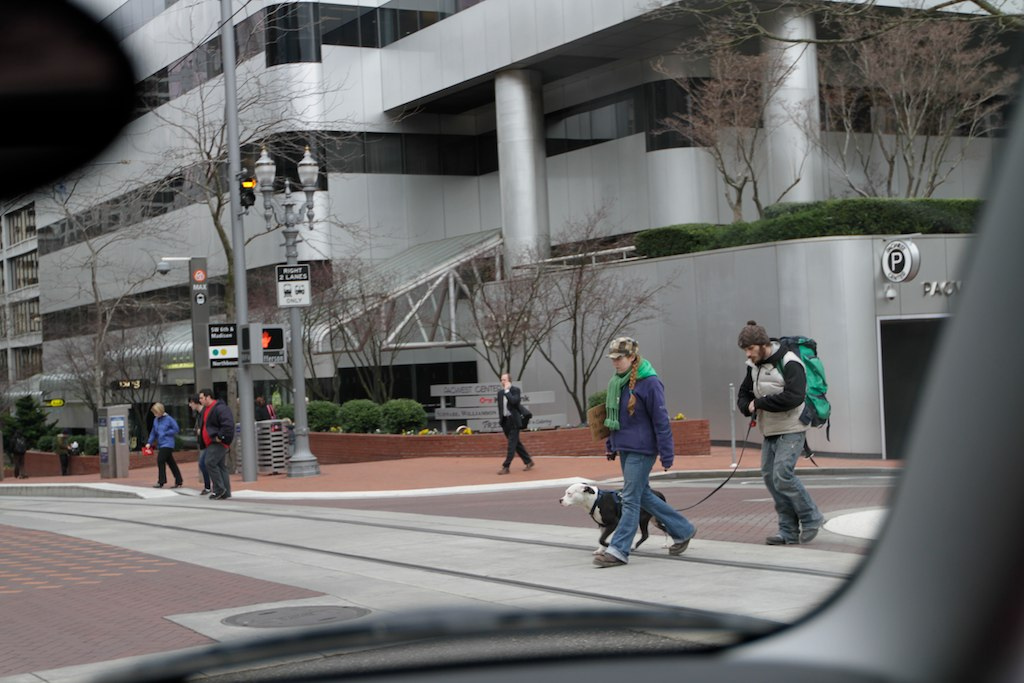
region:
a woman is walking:
[596, 340, 695, 560]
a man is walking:
[734, 321, 833, 534]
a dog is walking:
[561, 480, 660, 554]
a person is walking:
[494, 371, 532, 474]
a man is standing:
[196, 385, 236, 503]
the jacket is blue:
[147, 410, 179, 450]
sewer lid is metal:
[226, 599, 364, 631]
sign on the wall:
[880, 240, 919, 278]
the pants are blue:
[760, 436, 818, 528]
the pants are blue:
[608, 456, 688, 556]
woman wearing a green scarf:
[593, 337, 699, 566]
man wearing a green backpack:
[726, 319, 845, 547]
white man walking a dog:
[555, 318, 837, 562]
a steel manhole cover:
[215, 590, 383, 632]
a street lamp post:
[249, 142, 339, 476]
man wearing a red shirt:
[190, 386, 236, 501]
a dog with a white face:
[556, 478, 670, 556]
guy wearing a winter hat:
[735, 313, 838, 548]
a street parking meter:
[87, 397, 139, 487]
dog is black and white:
[559, 477, 668, 547]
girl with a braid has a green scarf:
[591, 338, 694, 566]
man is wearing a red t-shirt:
[198, 388, 238, 502]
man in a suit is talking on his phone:
[499, 372, 539, 472]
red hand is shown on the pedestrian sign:
[259, 323, 285, 361]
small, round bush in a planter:
[376, 398, 435, 431]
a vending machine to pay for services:
[97, 399, 139, 480]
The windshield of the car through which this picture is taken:
[4, 4, 1020, 663]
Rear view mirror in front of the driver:
[4, 5, 145, 215]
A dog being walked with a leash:
[562, 479, 670, 547]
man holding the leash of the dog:
[737, 320, 821, 548]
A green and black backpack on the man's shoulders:
[800, 337, 830, 430]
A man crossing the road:
[595, 334, 697, 566]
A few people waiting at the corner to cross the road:
[143, 381, 233, 496]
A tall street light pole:
[219, 5, 258, 476]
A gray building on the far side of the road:
[7, 8, 1022, 457]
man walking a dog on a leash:
[557, 316, 832, 548]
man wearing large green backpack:
[729, 312, 834, 546]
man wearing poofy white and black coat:
[729, 319, 835, 548]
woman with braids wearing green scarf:
[592, 334, 695, 566]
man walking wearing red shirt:
[191, 382, 240, 507]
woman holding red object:
[138, 398, 184, 488]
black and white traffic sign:
[273, 256, 315, 313]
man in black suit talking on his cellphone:
[491, 367, 534, 475]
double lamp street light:
[251, 141, 329, 481]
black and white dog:
[555, 474, 676, 548]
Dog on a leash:
[556, 475, 673, 543]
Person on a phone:
[487, 364, 551, 494]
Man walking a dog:
[723, 315, 850, 568]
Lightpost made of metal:
[245, 138, 354, 492]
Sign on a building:
[874, 236, 925, 284]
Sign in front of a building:
[419, 371, 572, 435]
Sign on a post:
[272, 257, 314, 318]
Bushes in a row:
[280, 386, 424, 434]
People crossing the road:
[132, 367, 256, 500]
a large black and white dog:
[554, 481, 665, 552]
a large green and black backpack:
[766, 338, 836, 431]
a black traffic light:
[228, 165, 266, 208]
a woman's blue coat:
[144, 410, 189, 448]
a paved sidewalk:
[1, 435, 877, 481]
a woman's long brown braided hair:
[626, 344, 642, 414]